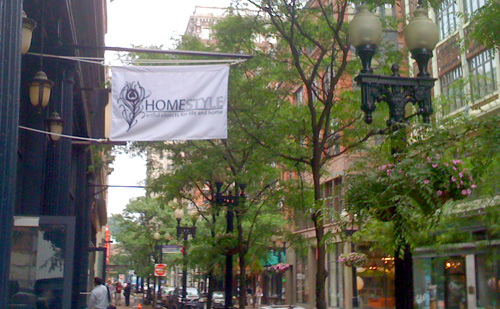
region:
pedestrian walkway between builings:
[56, 46, 456, 286]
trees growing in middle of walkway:
[117, 125, 452, 285]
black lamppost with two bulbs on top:
[330, 5, 460, 290]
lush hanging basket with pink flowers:
[350, 131, 475, 228]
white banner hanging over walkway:
[75, 31, 255, 157]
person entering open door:
[80, 235, 136, 305]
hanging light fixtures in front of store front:
[16, 10, 76, 147]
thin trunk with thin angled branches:
[270, 25, 351, 300]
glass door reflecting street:
[5, 211, 65, 301]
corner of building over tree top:
[180, 2, 235, 38]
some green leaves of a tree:
[354, 163, 439, 237]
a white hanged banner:
[117, 67, 230, 149]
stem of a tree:
[310, 228, 337, 290]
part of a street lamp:
[30, 71, 47, 114]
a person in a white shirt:
[84, 281, 113, 306]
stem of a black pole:
[394, 256, 416, 298]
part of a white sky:
[125, 6, 171, 29]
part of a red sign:
[148, 258, 168, 275]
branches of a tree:
[268, 10, 336, 180]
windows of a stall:
[427, 257, 474, 304]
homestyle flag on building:
[51, 36, 253, 162]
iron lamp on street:
[337, 3, 455, 145]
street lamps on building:
[29, 57, 71, 167]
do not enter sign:
[145, 257, 184, 301]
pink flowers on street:
[269, 252, 300, 288]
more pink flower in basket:
[334, 244, 369, 295]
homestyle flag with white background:
[90, 54, 244, 154]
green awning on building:
[243, 242, 286, 263]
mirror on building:
[4, 200, 94, 305]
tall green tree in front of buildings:
[208, 70, 291, 299]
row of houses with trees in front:
[200, 39, 479, 291]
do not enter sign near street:
[141, 238, 204, 287]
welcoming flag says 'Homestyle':
[116, 41, 233, 170]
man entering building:
[60, 259, 120, 304]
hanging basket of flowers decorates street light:
[322, 89, 489, 273]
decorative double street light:
[342, 0, 437, 165]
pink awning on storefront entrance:
[237, 203, 315, 300]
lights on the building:
[15, 6, 106, 228]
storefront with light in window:
[362, 202, 491, 300]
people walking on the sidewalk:
[109, 266, 154, 305]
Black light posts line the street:
[153, 5, 470, 236]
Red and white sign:
[151, 257, 178, 298]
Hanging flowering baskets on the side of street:
[251, 247, 415, 284]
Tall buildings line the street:
[199, 30, 473, 293]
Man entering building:
[78, 266, 118, 303]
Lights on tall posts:
[335, 13, 457, 68]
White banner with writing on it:
[89, 57, 284, 169]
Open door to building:
[8, 205, 122, 287]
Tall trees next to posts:
[120, 195, 391, 275]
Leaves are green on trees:
[123, 205, 465, 269]